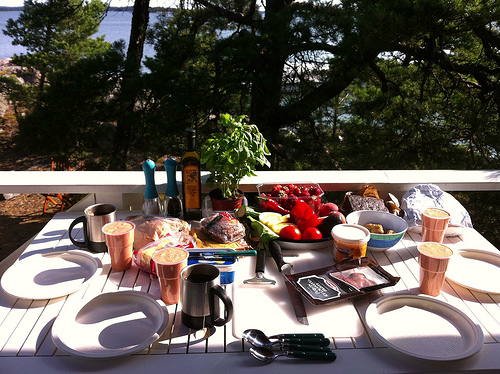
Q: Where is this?
A: This is at the porch.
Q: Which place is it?
A: It is a porch.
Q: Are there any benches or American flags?
A: No, there are no benches or American flags.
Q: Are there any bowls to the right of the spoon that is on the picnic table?
A: Yes, there is a bowl to the right of the spoon.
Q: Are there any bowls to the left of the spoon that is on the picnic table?
A: No, the bowl is to the right of the spoon.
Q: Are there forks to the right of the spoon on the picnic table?
A: No, there is a bowl to the right of the spoon.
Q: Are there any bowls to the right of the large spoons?
A: Yes, there is a bowl to the right of the spoons.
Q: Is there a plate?
A: Yes, there is a plate.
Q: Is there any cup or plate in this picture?
A: Yes, there is a plate.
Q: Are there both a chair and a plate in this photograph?
A: No, there is a plate but no chairs.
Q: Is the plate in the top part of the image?
A: No, the plate is in the bottom of the image.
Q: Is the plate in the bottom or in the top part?
A: The plate is in the bottom of the image.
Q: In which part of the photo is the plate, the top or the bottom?
A: The plate is in the bottom of the image.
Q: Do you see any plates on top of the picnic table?
A: Yes, there is a plate on top of the picnic table.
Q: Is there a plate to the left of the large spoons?
A: Yes, there is a plate to the left of the spoons.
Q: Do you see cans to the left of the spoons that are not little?
A: No, there is a plate to the left of the spoons.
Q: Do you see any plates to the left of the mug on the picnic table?
A: Yes, there is a plate to the left of the mug.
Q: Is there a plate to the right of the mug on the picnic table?
A: No, the plate is to the left of the mug.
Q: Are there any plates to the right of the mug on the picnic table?
A: No, the plate is to the left of the mug.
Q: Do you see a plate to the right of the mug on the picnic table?
A: No, the plate is to the left of the mug.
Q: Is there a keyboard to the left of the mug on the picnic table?
A: No, there is a plate to the left of the mug.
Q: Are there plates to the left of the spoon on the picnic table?
A: Yes, there is a plate to the left of the spoon.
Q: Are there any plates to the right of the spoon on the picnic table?
A: No, the plate is to the left of the spoon.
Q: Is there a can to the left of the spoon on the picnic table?
A: No, there is a plate to the left of the spoon.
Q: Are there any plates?
A: Yes, there is a plate.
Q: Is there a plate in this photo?
A: Yes, there is a plate.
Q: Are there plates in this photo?
A: Yes, there is a plate.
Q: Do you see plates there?
A: Yes, there is a plate.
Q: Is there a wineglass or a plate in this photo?
A: Yes, there is a plate.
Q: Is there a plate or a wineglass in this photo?
A: Yes, there is a plate.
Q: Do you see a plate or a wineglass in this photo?
A: Yes, there is a plate.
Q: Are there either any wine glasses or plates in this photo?
A: Yes, there is a plate.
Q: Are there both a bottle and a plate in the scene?
A: Yes, there are both a plate and a bottle.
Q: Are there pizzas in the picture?
A: No, there are no pizzas.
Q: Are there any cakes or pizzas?
A: No, there are no pizzas or cakes.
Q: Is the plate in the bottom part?
A: Yes, the plate is in the bottom of the image.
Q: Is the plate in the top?
A: No, the plate is in the bottom of the image.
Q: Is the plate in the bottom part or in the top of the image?
A: The plate is in the bottom of the image.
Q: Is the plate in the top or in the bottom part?
A: The plate is in the bottom of the image.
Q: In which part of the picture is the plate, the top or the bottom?
A: The plate is in the bottom of the image.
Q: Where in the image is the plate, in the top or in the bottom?
A: The plate is in the bottom of the image.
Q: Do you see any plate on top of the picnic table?
A: Yes, there is a plate on top of the picnic table.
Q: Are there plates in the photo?
A: Yes, there is a plate.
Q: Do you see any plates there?
A: Yes, there is a plate.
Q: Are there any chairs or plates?
A: Yes, there is a plate.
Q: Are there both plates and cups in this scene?
A: Yes, there are both a plate and a cup.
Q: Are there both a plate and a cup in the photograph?
A: Yes, there are both a plate and a cup.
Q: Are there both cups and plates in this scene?
A: Yes, there are both a plate and a cup.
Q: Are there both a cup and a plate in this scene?
A: Yes, there are both a plate and a cup.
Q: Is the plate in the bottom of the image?
A: Yes, the plate is in the bottom of the image.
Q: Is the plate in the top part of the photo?
A: No, the plate is in the bottom of the image.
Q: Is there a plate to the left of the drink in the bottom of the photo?
A: Yes, there is a plate to the left of the drink.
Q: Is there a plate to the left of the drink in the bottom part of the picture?
A: Yes, there is a plate to the left of the drink.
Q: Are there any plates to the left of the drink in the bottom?
A: Yes, there is a plate to the left of the drink.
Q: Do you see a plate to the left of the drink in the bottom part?
A: Yes, there is a plate to the left of the drink.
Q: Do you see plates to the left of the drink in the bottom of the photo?
A: Yes, there is a plate to the left of the drink.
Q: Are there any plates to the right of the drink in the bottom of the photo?
A: No, the plate is to the left of the drink.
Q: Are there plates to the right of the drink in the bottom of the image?
A: No, the plate is to the left of the drink.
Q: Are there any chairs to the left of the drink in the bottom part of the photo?
A: No, there is a plate to the left of the drink.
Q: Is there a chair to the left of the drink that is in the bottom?
A: No, there is a plate to the left of the drink.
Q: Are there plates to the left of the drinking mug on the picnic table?
A: Yes, there is a plate to the left of the mug.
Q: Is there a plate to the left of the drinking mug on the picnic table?
A: Yes, there is a plate to the left of the mug.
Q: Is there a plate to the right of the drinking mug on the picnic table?
A: No, the plate is to the left of the mug.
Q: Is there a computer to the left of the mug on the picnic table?
A: No, there is a plate to the left of the mug.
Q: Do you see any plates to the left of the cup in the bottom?
A: Yes, there is a plate to the left of the cup.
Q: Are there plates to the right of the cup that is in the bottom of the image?
A: No, the plate is to the left of the cup.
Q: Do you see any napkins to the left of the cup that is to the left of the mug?
A: No, there is a plate to the left of the cup.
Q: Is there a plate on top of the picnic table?
A: Yes, there is a plate on top of the picnic table.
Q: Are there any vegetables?
A: Yes, there are vegetables.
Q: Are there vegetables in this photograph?
A: Yes, there are vegetables.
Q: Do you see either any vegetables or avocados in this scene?
A: Yes, there are vegetables.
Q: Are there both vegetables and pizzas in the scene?
A: No, there are vegetables but no pizzas.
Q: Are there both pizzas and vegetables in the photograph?
A: No, there are vegetables but no pizzas.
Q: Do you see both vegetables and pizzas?
A: No, there are vegetables but no pizzas.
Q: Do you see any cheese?
A: No, there is no cheese.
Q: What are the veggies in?
A: The veggies are in the bowl.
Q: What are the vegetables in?
A: The veggies are in the bowl.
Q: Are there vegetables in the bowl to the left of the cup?
A: Yes, there are vegetables in the bowl.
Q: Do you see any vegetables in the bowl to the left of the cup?
A: Yes, there are vegetables in the bowl.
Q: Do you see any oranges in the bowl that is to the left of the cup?
A: No, there are vegetables in the bowl.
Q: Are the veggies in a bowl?
A: Yes, the veggies are in a bowl.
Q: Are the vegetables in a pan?
A: No, the vegetables are in a bowl.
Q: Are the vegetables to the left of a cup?
A: Yes, the vegetables are to the left of a cup.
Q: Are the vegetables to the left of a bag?
A: No, the vegetables are to the left of a cup.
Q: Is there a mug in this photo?
A: Yes, there is a mug.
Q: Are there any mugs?
A: Yes, there is a mug.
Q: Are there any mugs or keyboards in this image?
A: Yes, there is a mug.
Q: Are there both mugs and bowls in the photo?
A: Yes, there are both a mug and a bowl.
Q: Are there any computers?
A: No, there are no computers.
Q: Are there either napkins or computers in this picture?
A: No, there are no computers or napkins.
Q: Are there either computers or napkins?
A: No, there are no computers or napkins.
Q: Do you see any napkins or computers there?
A: No, there are no computers or napkins.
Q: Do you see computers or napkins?
A: No, there are no computers or napkins.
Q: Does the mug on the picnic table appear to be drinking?
A: Yes, the mug is drinking.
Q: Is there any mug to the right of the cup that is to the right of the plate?
A: Yes, there is a mug to the right of the cup.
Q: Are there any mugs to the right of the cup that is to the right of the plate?
A: Yes, there is a mug to the right of the cup.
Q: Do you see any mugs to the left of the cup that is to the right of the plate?
A: No, the mug is to the right of the cup.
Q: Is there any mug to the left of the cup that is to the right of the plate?
A: No, the mug is to the right of the cup.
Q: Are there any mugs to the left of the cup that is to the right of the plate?
A: No, the mug is to the right of the cup.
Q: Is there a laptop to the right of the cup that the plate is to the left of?
A: No, there is a mug to the right of the cup.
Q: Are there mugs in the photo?
A: Yes, there is a mug.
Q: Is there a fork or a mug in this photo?
A: Yes, there is a mug.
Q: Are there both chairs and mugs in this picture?
A: No, there is a mug but no chairs.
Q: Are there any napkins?
A: No, there are no napkins.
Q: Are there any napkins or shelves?
A: No, there are no napkins or shelves.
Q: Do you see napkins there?
A: No, there are no napkins.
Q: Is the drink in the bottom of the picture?
A: Yes, the drink is in the bottom of the image.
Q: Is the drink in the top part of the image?
A: No, the drink is in the bottom of the image.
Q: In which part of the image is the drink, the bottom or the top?
A: The drink is in the bottom of the image.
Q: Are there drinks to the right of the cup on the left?
A: Yes, there is a drink to the right of the cup.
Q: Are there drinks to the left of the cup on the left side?
A: No, the drink is to the right of the cup.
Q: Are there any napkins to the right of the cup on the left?
A: No, there is a drink to the right of the cup.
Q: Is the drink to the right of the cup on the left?
A: Yes, the drink is to the right of the cup.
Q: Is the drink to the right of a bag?
A: No, the drink is to the right of the cup.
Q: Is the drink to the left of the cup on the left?
A: No, the drink is to the right of the cup.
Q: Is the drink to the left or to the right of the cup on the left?
A: The drink is to the right of the cup.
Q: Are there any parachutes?
A: No, there are no parachutes.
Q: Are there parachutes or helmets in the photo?
A: No, there are no parachutes or helmets.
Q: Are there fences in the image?
A: No, there are no fences.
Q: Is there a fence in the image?
A: No, there are no fences.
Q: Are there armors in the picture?
A: No, there are no armors.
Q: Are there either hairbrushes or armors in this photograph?
A: No, there are no armors or hairbrushes.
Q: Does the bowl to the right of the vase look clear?
A: Yes, the bowl is clear.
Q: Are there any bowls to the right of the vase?
A: Yes, there is a bowl to the right of the vase.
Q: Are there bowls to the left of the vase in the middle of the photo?
A: No, the bowl is to the right of the vase.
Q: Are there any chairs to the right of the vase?
A: No, there is a bowl to the right of the vase.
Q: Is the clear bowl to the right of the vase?
A: Yes, the bowl is to the right of the vase.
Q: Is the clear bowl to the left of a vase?
A: No, the bowl is to the right of a vase.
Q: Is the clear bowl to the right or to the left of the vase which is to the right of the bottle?
A: The bowl is to the right of the vase.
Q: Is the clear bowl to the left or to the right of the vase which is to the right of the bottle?
A: The bowl is to the right of the vase.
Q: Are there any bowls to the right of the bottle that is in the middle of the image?
A: Yes, there is a bowl to the right of the bottle.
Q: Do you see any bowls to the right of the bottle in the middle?
A: Yes, there is a bowl to the right of the bottle.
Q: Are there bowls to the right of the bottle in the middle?
A: Yes, there is a bowl to the right of the bottle.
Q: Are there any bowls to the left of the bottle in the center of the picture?
A: No, the bowl is to the right of the bottle.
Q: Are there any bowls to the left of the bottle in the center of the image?
A: No, the bowl is to the right of the bottle.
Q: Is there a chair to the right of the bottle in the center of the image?
A: No, there is a bowl to the right of the bottle.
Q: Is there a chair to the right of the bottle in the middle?
A: No, there is a bowl to the right of the bottle.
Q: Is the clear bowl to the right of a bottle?
A: Yes, the bowl is to the right of a bottle.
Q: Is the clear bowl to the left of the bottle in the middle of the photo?
A: No, the bowl is to the right of the bottle.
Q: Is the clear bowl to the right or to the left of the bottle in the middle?
A: The bowl is to the right of the bottle.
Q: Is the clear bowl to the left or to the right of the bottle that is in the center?
A: The bowl is to the right of the bottle.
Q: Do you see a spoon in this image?
A: Yes, there is a spoon.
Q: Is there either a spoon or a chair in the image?
A: Yes, there is a spoon.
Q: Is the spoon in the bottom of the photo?
A: Yes, the spoon is in the bottom of the image.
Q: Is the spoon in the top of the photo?
A: No, the spoon is in the bottom of the image.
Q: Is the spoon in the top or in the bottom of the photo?
A: The spoon is in the bottom of the image.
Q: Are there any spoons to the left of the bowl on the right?
A: Yes, there is a spoon to the left of the bowl.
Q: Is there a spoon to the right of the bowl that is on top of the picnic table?
A: No, the spoon is to the left of the bowl.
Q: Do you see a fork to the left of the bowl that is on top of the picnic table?
A: No, there is a spoon to the left of the bowl.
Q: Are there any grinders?
A: No, there are no grinders.